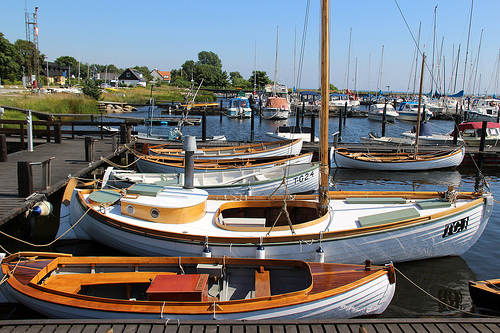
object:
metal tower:
[24, 1, 38, 93]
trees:
[247, 70, 271, 91]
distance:
[11, 46, 476, 98]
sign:
[441, 216, 470, 239]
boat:
[329, 144, 466, 171]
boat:
[149, 137, 304, 158]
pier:
[0, 317, 500, 332]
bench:
[253, 269, 270, 298]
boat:
[133, 151, 314, 173]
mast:
[318, 0, 330, 217]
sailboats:
[67, 133, 495, 266]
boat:
[113, 160, 338, 196]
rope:
[391, 265, 499, 317]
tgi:
[441, 216, 469, 239]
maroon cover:
[449, 121, 500, 138]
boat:
[449, 121, 500, 147]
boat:
[0, 250, 397, 320]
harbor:
[0, 90, 500, 320]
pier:
[0, 114, 139, 228]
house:
[147, 67, 171, 87]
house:
[117, 67, 147, 88]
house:
[90, 72, 121, 87]